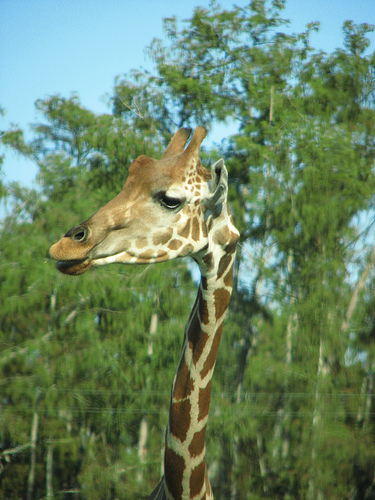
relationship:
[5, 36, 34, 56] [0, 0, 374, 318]
white clouds in sky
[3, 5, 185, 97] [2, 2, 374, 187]
clouds in sky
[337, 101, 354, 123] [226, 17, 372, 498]
leaf in tree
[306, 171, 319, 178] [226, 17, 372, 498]
leaf in tree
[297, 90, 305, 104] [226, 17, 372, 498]
leaf in tree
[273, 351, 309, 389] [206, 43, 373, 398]
leaves in tree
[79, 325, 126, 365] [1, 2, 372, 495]
leaves in tree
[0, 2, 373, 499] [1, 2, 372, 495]
leaves in tree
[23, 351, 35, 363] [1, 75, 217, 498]
leaf in tree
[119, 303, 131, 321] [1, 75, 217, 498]
leaf in tree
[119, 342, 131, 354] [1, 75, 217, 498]
leaf in tree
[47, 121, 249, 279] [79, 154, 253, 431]
head of giraffe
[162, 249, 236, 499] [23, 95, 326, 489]
neck of giraffe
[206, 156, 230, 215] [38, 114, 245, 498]
ear of giraffe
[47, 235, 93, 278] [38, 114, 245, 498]
jaw of giraffe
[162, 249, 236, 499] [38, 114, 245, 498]
neck of giraffe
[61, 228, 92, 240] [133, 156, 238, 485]
nose of giraffe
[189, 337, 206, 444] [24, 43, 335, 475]
skin of giraffe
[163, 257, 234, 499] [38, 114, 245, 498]
neck of giraffe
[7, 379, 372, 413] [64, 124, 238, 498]
fence behind giraffee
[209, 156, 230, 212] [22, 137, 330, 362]
ear of giraffe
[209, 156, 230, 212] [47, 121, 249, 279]
ear near back of head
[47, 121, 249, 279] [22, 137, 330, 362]
head of giraffe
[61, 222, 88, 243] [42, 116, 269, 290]
nose on giraffe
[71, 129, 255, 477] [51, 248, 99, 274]
giraffe has mouth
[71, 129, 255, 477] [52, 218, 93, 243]
giraffe has nose